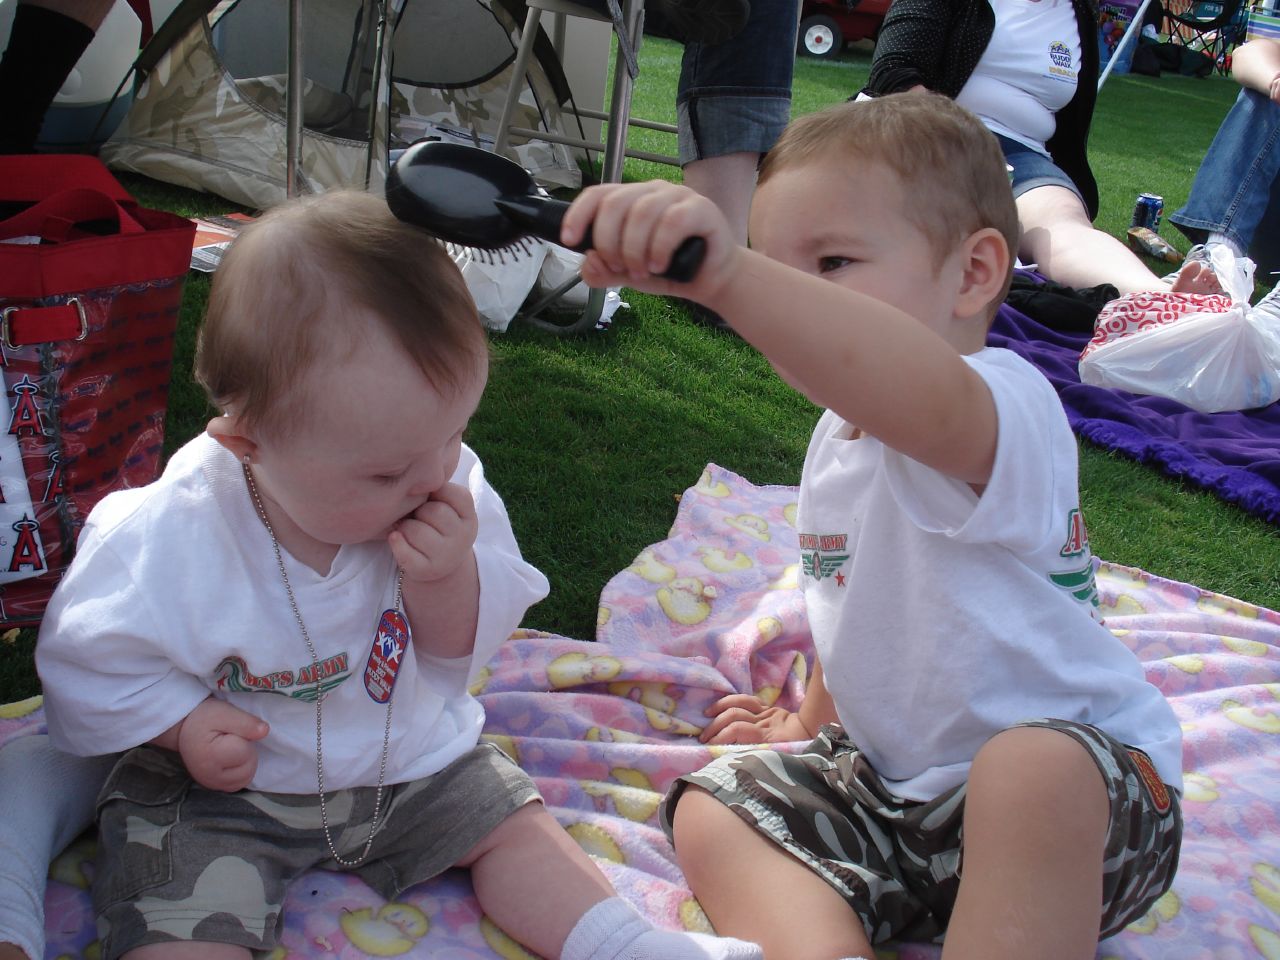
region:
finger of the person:
[603, 207, 628, 232]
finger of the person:
[568, 194, 610, 234]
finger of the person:
[415, 505, 455, 512]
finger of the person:
[407, 531, 447, 560]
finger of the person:
[237, 706, 273, 740]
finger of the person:
[217, 741, 260, 790]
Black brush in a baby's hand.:
[376, 126, 719, 279]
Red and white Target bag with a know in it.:
[1097, 265, 1272, 418]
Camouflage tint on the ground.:
[124, 9, 581, 235]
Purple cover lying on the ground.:
[1148, 434, 1276, 525]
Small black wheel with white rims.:
[804, 9, 847, 60]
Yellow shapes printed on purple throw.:
[632, 551, 738, 646]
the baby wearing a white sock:
[32, 181, 763, 956]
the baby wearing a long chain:
[36, 192, 758, 958]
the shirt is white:
[34, 424, 551, 787]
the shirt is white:
[797, 340, 1186, 802]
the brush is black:
[385, 136, 708, 287]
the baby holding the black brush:
[384, 92, 1186, 958]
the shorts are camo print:
[660, 723, 1182, 955]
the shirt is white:
[949, 4, 1084, 157]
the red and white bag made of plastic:
[1078, 243, 1277, 416]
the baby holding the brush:
[391, 86, 1180, 956]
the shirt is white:
[800, 340, 1187, 806]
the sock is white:
[557, 887, 761, 958]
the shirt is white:
[29, 406, 551, 795]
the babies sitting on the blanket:
[5, 84, 1277, 954]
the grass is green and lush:
[3, 26, 1277, 709]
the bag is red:
[1, 152, 194, 634]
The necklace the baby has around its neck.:
[266, 532, 419, 886]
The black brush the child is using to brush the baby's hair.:
[398, 139, 716, 285]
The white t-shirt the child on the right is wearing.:
[742, 333, 1195, 782]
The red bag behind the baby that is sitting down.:
[0, 146, 164, 672]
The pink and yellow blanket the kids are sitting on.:
[36, 472, 1272, 943]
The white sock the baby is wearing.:
[552, 907, 786, 958]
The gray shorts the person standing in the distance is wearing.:
[680, 102, 786, 167]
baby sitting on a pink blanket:
[42, 200, 769, 955]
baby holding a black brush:
[382, 128, 696, 288]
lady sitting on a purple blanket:
[859, 0, 1175, 307]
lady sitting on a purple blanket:
[1168, 16, 1270, 266]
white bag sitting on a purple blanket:
[1078, 232, 1268, 413]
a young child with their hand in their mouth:
[212, 212, 513, 581]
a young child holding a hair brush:
[343, 108, 906, 327]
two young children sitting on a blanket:
[31, 144, 1131, 952]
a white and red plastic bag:
[1100, 252, 1273, 416]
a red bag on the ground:
[0, 152, 224, 583]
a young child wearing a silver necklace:
[252, 475, 445, 860]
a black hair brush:
[385, 130, 624, 258]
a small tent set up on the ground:
[119, 3, 638, 238]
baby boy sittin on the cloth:
[217, 219, 496, 822]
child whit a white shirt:
[769, 168, 1103, 809]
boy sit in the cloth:
[763, 31, 1187, 894]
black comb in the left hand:
[389, 113, 696, 270]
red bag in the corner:
[19, 205, 174, 439]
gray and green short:
[109, 750, 558, 894]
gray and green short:
[789, 742, 940, 879]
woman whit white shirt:
[946, 11, 1088, 104]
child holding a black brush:
[383, 90, 1187, 956]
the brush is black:
[384, 137, 705, 283]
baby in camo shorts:
[32, 189, 761, 958]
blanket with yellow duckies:
[0, 463, 1274, 958]